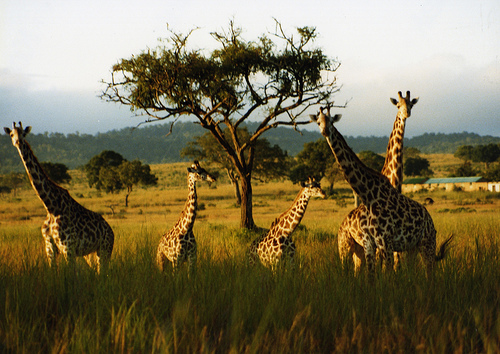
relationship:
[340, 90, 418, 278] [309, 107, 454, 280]
giraffe blocked by giraffe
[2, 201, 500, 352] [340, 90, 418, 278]
grass in front of giraffe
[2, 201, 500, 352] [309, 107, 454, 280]
grass in front of giraffe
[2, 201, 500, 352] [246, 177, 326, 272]
grass in front of giraffe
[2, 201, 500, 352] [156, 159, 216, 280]
grass in front of giraffe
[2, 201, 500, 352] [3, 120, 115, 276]
grass in front of giraffe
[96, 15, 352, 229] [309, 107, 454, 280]
tree behind giraffe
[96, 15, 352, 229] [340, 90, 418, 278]
tree behind giraffe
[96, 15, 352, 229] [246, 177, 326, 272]
tree behind giraffe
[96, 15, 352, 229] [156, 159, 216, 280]
tree behind giraffe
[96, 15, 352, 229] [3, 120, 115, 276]
tree behind giraffe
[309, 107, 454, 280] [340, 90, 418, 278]
giraffe in front of giraffe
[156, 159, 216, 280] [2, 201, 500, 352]
giraffe standing in grass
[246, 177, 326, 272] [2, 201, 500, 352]
giraffe standing in grass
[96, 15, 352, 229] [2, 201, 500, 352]
tree in grass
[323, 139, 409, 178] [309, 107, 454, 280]
necks on giraffe